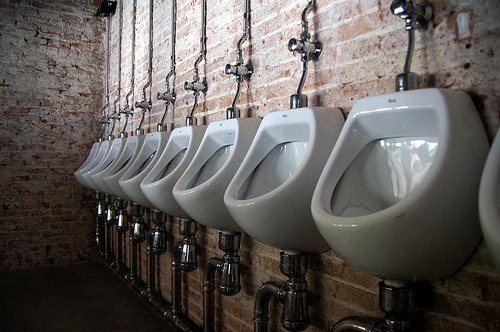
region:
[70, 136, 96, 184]
white urinal on brick wall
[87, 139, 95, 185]
white urinal on brick wall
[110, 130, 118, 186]
white urinal on brick wall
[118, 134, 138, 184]
white urinal on brick wall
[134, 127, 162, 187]
white urinal on brick wall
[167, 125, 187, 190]
white urinal on brick wall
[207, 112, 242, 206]
white urinal on brick wall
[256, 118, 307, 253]
white urinal on brick wall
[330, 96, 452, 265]
white urinal on brick wall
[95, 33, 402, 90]
metal pipes leading to urinals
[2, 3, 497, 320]
wall is made of brick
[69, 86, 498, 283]
urinals lined on the wall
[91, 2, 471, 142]
silver pipes above urinals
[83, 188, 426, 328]
silver pipes below urinals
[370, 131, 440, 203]
reflection on the urinal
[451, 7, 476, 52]
white spot on the brick wall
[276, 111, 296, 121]
gray words on urinal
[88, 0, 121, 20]
black object on brick wall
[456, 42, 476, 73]
black spots on brick wall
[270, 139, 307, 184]
reflection on the urinal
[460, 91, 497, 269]
Small white urnal on the wall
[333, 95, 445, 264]
Small white urnal on the wall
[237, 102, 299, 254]
Small white urnal on the wall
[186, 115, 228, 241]
Small white urnal on the wall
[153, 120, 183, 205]
Small white urnal on the wall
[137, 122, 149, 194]
Small white urnal on the wall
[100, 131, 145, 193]
Small white urnal on the wall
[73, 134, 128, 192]
Small white urnal on the wall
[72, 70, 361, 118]
Metal piping on a brick wall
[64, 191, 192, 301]
Metal piping on a brick wall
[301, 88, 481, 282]
white urinal in men's room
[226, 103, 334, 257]
white urinal in men's room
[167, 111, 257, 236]
white urinal in men's room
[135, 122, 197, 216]
white urinal in men's room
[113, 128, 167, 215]
white urinal in men's room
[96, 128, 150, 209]
white urinal in men's room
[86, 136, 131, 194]
white urinal in men's room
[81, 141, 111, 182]
white urinal in men's room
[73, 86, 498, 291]
white urinals in men's room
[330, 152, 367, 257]
There is a white urinal pictured here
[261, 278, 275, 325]
There is a stainless steel pump here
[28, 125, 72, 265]
There is a brick wall pictured here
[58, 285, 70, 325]
There is a brown floor visible here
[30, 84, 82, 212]
Jackson Mingus took this photo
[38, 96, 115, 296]
This photo has a great deal of detail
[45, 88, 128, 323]
This photo is quite striking here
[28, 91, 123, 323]
This photo was taken in the summer season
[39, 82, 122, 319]
This photo is actually quite picturesque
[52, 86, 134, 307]
This photo has a lovely light to it